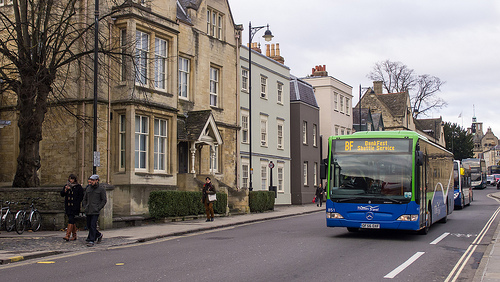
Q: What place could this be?
A: It is a street.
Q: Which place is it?
A: It is a street.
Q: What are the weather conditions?
A: It is cloudy.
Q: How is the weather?
A: It is cloudy.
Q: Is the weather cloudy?
A: Yes, it is cloudy.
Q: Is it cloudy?
A: Yes, it is cloudy.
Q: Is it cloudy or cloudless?
A: It is cloudy.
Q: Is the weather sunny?
A: No, it is cloudy.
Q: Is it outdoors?
A: Yes, it is outdoors.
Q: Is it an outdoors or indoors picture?
A: It is outdoors.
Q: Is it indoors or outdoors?
A: It is outdoors.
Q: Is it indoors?
A: No, it is outdoors.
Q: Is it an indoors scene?
A: No, it is outdoors.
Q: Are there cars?
A: No, there are no cars.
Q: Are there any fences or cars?
A: No, there are no cars or fences.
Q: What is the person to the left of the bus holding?
A: The person is holding the bag.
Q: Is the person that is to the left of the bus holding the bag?
A: Yes, the person is holding the bag.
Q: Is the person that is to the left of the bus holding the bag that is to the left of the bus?
A: Yes, the person is holding the bag.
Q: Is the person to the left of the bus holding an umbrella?
A: No, the person is holding the bag.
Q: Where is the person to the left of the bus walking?
A: The person is walking on the pavement.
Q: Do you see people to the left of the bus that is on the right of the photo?
A: Yes, there is a person to the left of the bus.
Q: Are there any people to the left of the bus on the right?
A: Yes, there is a person to the left of the bus.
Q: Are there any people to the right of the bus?
A: No, the person is to the left of the bus.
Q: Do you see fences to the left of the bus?
A: No, there is a person to the left of the bus.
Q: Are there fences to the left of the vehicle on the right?
A: No, there is a person to the left of the bus.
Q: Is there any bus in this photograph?
A: Yes, there is a bus.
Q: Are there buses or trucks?
A: Yes, there is a bus.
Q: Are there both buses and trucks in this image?
A: No, there is a bus but no trucks.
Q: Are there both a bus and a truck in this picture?
A: No, there is a bus but no trucks.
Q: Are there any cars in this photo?
A: No, there are no cars.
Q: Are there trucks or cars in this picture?
A: No, there are no cars or trucks.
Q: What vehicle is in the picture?
A: The vehicle is a bus.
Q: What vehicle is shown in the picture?
A: The vehicle is a bus.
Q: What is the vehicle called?
A: The vehicle is a bus.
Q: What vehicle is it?
A: The vehicle is a bus.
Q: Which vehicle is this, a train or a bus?
A: This is a bus.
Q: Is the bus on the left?
A: No, the bus is on the right of the image.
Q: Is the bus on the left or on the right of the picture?
A: The bus is on the right of the image.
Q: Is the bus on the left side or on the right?
A: The bus is on the right of the image.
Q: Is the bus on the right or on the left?
A: The bus is on the right of the image.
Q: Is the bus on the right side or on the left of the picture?
A: The bus is on the right of the image.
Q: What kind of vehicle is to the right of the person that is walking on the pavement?
A: The vehicle is a bus.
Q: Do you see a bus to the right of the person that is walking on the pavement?
A: Yes, there is a bus to the right of the person.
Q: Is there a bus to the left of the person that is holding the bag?
A: No, the bus is to the right of the person.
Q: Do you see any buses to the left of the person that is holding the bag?
A: No, the bus is to the right of the person.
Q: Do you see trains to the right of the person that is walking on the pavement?
A: No, there is a bus to the right of the person.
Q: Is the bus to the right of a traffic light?
A: No, the bus is to the right of the person.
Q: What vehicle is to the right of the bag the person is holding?
A: The vehicle is a bus.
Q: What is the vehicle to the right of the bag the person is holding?
A: The vehicle is a bus.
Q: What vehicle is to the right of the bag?
A: The vehicle is a bus.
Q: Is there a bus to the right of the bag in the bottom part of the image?
A: Yes, there is a bus to the right of the bag.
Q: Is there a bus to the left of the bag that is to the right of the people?
A: No, the bus is to the right of the bag.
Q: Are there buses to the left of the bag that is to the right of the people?
A: No, the bus is to the right of the bag.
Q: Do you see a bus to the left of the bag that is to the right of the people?
A: No, the bus is to the right of the bag.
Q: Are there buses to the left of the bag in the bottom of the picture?
A: No, the bus is to the right of the bag.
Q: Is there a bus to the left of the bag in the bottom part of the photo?
A: No, the bus is to the right of the bag.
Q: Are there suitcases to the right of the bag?
A: No, there is a bus to the right of the bag.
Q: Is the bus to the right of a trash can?
A: No, the bus is to the right of the bag.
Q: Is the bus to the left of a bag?
A: No, the bus is to the right of a bag.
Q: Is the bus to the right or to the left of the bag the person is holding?
A: The bus is to the right of the bag.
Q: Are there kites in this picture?
A: No, there are no kites.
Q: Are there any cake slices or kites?
A: No, there are no kites or cake slices.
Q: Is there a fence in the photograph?
A: No, there are no fences.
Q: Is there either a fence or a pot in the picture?
A: No, there are no fences or pots.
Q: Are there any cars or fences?
A: No, there are no fences or cars.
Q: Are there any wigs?
A: No, there are no wigs.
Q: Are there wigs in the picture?
A: No, there are no wigs.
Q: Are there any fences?
A: No, there are no fences.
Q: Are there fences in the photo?
A: No, there are no fences.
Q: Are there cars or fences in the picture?
A: No, there are no fences or cars.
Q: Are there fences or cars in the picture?
A: No, there are no fences or cars.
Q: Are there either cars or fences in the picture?
A: No, there are no fences or cars.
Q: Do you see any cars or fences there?
A: No, there are no fences or cars.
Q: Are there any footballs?
A: No, there are no footballs.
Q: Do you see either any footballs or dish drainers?
A: No, there are no footballs or dish drainers.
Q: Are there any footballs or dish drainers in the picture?
A: No, there are no footballs or dish drainers.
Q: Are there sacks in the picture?
A: No, there are no sacks.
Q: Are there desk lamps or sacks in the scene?
A: No, there are no sacks or desk lamps.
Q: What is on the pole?
A: The street lamp is on the pole.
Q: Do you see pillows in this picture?
A: No, there are no pillows.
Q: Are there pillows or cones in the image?
A: No, there are no pillows or cones.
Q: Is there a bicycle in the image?
A: Yes, there is a bicycle.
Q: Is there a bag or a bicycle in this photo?
A: Yes, there is a bicycle.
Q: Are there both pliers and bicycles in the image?
A: No, there is a bicycle but no pliers.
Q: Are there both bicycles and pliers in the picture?
A: No, there is a bicycle but no pliers.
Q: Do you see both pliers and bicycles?
A: No, there is a bicycle but no pliers.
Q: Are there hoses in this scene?
A: No, there are no hoses.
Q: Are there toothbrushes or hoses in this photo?
A: No, there are no hoses or toothbrushes.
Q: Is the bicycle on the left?
A: Yes, the bicycle is on the left of the image.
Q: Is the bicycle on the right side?
A: No, the bicycle is on the left of the image.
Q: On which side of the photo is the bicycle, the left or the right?
A: The bicycle is on the left of the image.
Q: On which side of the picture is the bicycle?
A: The bicycle is on the left of the image.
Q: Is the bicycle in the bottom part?
A: Yes, the bicycle is in the bottom of the image.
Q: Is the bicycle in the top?
A: No, the bicycle is in the bottom of the image.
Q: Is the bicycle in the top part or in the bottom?
A: The bicycle is in the bottom of the image.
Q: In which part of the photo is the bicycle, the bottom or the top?
A: The bicycle is in the bottom of the image.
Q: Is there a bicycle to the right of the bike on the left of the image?
A: Yes, there is a bicycle to the right of the bike.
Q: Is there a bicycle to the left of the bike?
A: No, the bicycle is to the right of the bike.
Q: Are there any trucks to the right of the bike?
A: No, there is a bicycle to the right of the bike.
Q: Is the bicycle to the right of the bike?
A: Yes, the bicycle is to the right of the bike.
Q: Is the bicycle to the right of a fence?
A: No, the bicycle is to the right of the bike.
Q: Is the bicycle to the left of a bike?
A: No, the bicycle is to the right of a bike.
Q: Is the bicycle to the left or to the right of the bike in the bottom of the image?
A: The bicycle is to the right of the bike.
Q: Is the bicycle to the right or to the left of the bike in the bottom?
A: The bicycle is to the right of the bike.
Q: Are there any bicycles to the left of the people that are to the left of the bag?
A: Yes, there is a bicycle to the left of the people.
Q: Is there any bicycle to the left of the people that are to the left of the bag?
A: Yes, there is a bicycle to the left of the people.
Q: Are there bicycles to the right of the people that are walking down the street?
A: No, the bicycle is to the left of the people.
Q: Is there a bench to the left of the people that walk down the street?
A: No, there is a bicycle to the left of the people.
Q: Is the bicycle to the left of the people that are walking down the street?
A: Yes, the bicycle is to the left of the people.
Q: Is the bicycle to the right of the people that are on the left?
A: No, the bicycle is to the left of the people.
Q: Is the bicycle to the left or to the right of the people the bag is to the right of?
A: The bicycle is to the left of the people.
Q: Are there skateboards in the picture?
A: No, there are no skateboards.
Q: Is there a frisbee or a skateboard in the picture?
A: No, there are no skateboards or frisbees.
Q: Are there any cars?
A: No, there are no cars.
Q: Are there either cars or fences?
A: No, there are no cars or fences.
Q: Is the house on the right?
A: Yes, the house is on the right of the image.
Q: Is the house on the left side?
A: No, the house is on the right of the image.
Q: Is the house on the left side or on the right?
A: The house is on the right of the image.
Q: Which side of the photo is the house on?
A: The house is on the right of the image.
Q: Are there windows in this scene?
A: Yes, there are windows.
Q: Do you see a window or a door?
A: Yes, there are windows.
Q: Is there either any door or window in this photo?
A: Yes, there are windows.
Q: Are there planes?
A: No, there are no planes.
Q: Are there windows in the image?
A: Yes, there are windows.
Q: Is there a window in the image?
A: Yes, there are windows.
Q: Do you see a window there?
A: Yes, there are windows.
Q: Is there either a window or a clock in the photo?
A: Yes, there are windows.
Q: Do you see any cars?
A: No, there are no cars.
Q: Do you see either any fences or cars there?
A: No, there are no cars or fences.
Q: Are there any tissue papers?
A: No, there are no tissue papers.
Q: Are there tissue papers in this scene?
A: No, there are no tissue papers.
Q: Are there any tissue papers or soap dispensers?
A: No, there are no tissue papers or soap dispensers.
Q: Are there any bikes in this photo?
A: Yes, there is a bike.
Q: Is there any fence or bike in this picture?
A: Yes, there is a bike.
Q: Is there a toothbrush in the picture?
A: No, there are no toothbrushes.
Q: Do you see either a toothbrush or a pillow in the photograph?
A: No, there are no toothbrushes or pillows.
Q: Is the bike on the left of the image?
A: Yes, the bike is on the left of the image.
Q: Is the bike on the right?
A: No, the bike is on the left of the image.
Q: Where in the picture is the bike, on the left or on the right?
A: The bike is on the left of the image.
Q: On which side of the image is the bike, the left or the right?
A: The bike is on the left of the image.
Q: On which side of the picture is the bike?
A: The bike is on the left of the image.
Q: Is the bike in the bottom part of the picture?
A: Yes, the bike is in the bottom of the image.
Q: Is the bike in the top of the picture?
A: No, the bike is in the bottom of the image.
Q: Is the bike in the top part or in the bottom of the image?
A: The bike is in the bottom of the image.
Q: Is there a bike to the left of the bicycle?
A: Yes, there is a bike to the left of the bicycle.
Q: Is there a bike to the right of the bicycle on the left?
A: No, the bike is to the left of the bicycle.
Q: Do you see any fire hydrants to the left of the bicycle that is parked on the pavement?
A: No, there is a bike to the left of the bicycle.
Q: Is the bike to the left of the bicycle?
A: Yes, the bike is to the left of the bicycle.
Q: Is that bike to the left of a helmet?
A: No, the bike is to the left of the bicycle.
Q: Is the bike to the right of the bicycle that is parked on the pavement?
A: No, the bike is to the left of the bicycle.